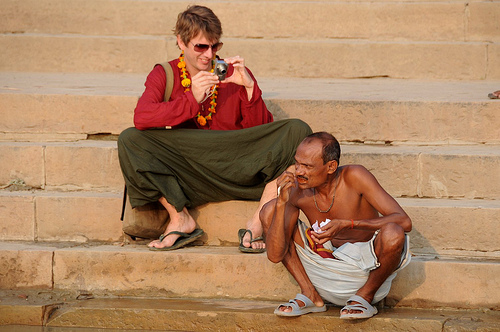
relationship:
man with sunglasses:
[118, 5, 313, 249] [188, 37, 223, 53]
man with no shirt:
[260, 131, 414, 320] [134, 56, 273, 129]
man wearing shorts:
[260, 131, 414, 320] [294, 220, 416, 308]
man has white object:
[260, 131, 414, 320] [314, 217, 334, 233]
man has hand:
[260, 131, 414, 320] [278, 170, 297, 200]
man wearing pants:
[118, 5, 313, 249] [117, 118, 315, 211]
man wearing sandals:
[118, 5, 313, 249] [147, 228, 269, 255]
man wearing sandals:
[260, 131, 414, 320] [274, 291, 380, 320]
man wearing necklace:
[118, 5, 313, 249] [176, 55, 219, 127]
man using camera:
[118, 5, 313, 249] [213, 60, 229, 82]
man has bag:
[118, 5, 313, 249] [121, 191, 169, 239]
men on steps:
[115, 5, 414, 322] [1, 1, 494, 329]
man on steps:
[260, 131, 414, 320] [1, 1, 494, 329]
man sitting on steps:
[118, 5, 313, 249] [1, 1, 494, 329]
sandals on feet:
[147, 228, 269, 255] [153, 212, 267, 250]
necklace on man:
[310, 184, 339, 214] [260, 131, 414, 320]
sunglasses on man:
[188, 37, 223, 53] [118, 5, 313, 249]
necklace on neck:
[176, 55, 219, 127] [181, 61, 202, 75]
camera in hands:
[213, 60, 229, 82] [192, 56, 256, 103]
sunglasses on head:
[188, 37, 223, 53] [174, 7, 223, 72]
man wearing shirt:
[118, 5, 313, 249] [134, 56, 273, 129]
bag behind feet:
[121, 191, 169, 239] [153, 212, 267, 250]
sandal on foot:
[276, 293, 328, 317] [277, 298, 325, 309]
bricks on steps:
[420, 143, 500, 199] [1, 1, 494, 329]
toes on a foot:
[146, 239, 165, 248] [147, 216, 198, 249]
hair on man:
[174, 6, 221, 33] [118, 5, 313, 249]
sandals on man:
[147, 228, 269, 255] [118, 5, 313, 249]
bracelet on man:
[350, 215, 357, 227] [260, 131, 414, 320]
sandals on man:
[274, 291, 380, 320] [260, 131, 414, 320]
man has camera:
[118, 5, 313, 249] [213, 60, 229, 82]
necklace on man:
[176, 55, 219, 127] [118, 5, 313, 249]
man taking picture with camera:
[118, 5, 313, 249] [213, 60, 229, 82]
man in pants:
[118, 5, 313, 249] [117, 118, 315, 211]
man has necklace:
[118, 5, 313, 249] [176, 55, 219, 127]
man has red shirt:
[118, 5, 313, 249] [134, 56, 273, 129]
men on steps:
[119, 6, 413, 321] [1, 1, 494, 329]